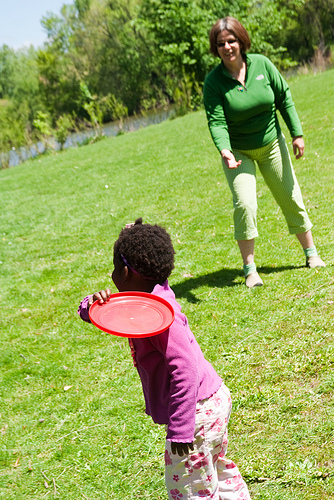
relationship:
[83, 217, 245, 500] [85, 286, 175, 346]
child holding frisbee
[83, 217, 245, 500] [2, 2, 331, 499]
child playing outside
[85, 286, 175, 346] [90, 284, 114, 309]
frisbee in hand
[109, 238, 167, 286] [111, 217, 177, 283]
headband in hair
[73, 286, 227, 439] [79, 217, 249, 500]
shirt on child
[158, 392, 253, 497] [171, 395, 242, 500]
pants with flowers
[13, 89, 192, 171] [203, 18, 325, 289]
water behind lady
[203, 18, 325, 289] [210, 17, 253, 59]
lady with hair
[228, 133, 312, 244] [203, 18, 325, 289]
capris on lady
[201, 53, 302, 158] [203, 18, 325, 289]
shirt on lady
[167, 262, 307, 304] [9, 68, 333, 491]
shadow on grass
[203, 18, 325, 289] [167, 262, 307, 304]
lady has shadow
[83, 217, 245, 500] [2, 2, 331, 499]
child standing outside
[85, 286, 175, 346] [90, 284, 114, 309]
frisbee on hand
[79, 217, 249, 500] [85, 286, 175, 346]
child holding frisbee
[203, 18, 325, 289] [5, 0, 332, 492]
lady playing frisbee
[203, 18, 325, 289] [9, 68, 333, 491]
lady playing in grass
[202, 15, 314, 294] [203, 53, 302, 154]
lady wearing shirt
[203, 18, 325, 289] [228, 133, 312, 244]
lady wearing capris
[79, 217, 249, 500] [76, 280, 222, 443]
child wearing shirt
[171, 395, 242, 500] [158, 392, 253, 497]
flowers on pants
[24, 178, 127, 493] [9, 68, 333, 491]
leaves on grass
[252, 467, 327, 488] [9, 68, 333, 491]
branches on grass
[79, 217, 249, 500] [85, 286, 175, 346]
child throws frisbee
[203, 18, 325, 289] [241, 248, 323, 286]
lady wearing socks